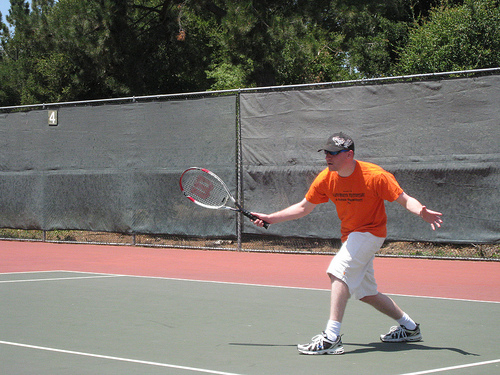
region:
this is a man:
[251, 137, 441, 359]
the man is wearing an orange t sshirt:
[301, 165, 387, 239]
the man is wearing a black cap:
[322, 131, 357, 173]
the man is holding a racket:
[168, 160, 285, 228]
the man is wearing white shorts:
[330, 229, 385, 306]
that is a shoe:
[294, 328, 346, 361]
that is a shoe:
[379, 325, 428, 345]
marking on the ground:
[97, 351, 122, 368]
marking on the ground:
[28, 340, 54, 355]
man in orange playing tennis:
[248, 131, 441, 353]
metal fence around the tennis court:
[0, 67, 499, 262]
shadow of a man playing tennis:
[231, 341, 479, 358]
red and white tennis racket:
[180, 166, 268, 228]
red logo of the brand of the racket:
[188, 175, 212, 200]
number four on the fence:
[49, 111, 55, 123]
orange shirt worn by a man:
[304, 160, 402, 240]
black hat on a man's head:
[318, 131, 355, 154]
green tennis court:
[0, 268, 499, 373]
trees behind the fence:
[0, 0, 499, 112]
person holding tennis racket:
[173, 119, 458, 361]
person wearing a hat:
[313, 130, 368, 181]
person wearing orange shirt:
[179, 122, 451, 343]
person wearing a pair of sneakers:
[176, 127, 447, 357]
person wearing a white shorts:
[177, 127, 443, 361]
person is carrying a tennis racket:
[174, 120, 446, 356]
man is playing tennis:
[175, 122, 450, 359]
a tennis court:
[1, 255, 499, 372]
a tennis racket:
[172, 163, 274, 235]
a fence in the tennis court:
[3, 67, 498, 254]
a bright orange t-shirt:
[306, 162, 401, 233]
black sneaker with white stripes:
[300, 331, 345, 357]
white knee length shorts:
[327, 228, 383, 297]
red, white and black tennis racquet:
[176, 163, 262, 224]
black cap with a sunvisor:
[316, 125, 347, 155]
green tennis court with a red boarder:
[0, 240, 490, 370]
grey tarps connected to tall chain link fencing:
[0, 65, 495, 240]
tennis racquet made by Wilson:
[178, 161, 273, 227]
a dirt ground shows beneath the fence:
[0, 221, 495, 253]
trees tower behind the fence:
[8, 2, 498, 105]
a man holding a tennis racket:
[166, 123, 447, 359]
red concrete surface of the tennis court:
[225, 260, 300, 280]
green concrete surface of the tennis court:
[121, 301, 238, 346]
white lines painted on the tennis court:
[37, 254, 115, 289]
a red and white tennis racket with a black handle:
[174, 155, 276, 228]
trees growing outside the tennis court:
[31, 0, 413, 74]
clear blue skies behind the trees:
[1, 0, 41, 36]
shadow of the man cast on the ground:
[335, 332, 474, 364]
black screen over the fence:
[83, 119, 176, 238]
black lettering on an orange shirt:
[324, 185, 373, 208]